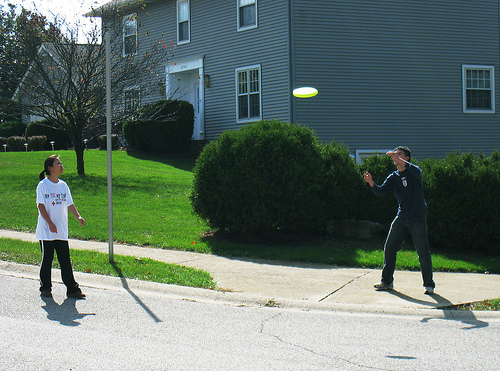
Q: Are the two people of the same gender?
A: No, they are both male and female.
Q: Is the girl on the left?
A: Yes, the girl is on the left of the image.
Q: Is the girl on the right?
A: No, the girl is on the left of the image.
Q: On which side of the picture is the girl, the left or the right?
A: The girl is on the left of the image.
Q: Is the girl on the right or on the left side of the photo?
A: The girl is on the left of the image.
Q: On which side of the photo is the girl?
A: The girl is on the left of the image.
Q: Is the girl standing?
A: Yes, the girl is standing.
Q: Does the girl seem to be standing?
A: Yes, the girl is standing.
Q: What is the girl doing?
A: The girl is standing.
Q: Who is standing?
A: The girl is standing.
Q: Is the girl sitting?
A: No, the girl is standing.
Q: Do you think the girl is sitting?
A: No, the girl is standing.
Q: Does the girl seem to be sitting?
A: No, the girl is standing.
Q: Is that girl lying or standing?
A: The girl is standing.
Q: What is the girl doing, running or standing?
A: The girl is standing.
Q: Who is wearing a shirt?
A: The girl is wearing a shirt.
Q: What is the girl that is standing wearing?
A: The girl is wearing a shirt.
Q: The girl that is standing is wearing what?
A: The girl is wearing a shirt.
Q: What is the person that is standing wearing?
A: The girl is wearing a shirt.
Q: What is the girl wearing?
A: The girl is wearing a shirt.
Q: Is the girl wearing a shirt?
A: Yes, the girl is wearing a shirt.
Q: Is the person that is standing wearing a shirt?
A: Yes, the girl is wearing a shirt.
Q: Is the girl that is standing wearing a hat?
A: No, the girl is wearing a shirt.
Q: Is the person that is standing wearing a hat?
A: No, the girl is wearing a shirt.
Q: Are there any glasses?
A: No, there are no glasses.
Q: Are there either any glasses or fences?
A: No, there are no glasses or fences.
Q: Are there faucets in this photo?
A: No, there are no faucets.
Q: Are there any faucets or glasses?
A: No, there are no faucets or glasses.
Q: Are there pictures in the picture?
A: No, there are no pictures.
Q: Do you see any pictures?
A: No, there are no pictures.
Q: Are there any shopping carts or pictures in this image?
A: No, there are no pictures or shopping carts.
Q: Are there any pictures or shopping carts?
A: No, there are no pictures or shopping carts.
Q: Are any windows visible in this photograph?
A: Yes, there is a window.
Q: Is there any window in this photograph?
A: Yes, there is a window.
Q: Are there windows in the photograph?
A: Yes, there is a window.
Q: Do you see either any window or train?
A: Yes, there is a window.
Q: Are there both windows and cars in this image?
A: No, there is a window but no cars.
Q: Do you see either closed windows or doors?
A: Yes, there is a closed window.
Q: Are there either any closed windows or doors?
A: Yes, there is a closed window.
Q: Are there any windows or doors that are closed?
A: Yes, the window is closed.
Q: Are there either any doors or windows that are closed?
A: Yes, the window is closed.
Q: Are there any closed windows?
A: Yes, there is a closed window.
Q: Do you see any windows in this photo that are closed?
A: Yes, there is a window that is closed.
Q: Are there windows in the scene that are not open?
A: Yes, there is an closed window.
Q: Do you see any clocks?
A: No, there are no clocks.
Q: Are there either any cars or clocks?
A: No, there are no clocks or cars.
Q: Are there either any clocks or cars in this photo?
A: No, there are no clocks or cars.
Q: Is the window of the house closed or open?
A: The window is closed.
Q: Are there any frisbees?
A: Yes, there is a frisbee.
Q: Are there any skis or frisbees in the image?
A: Yes, there is a frisbee.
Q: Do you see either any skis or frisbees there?
A: Yes, there is a frisbee.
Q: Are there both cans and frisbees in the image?
A: No, there is a frisbee but no cans.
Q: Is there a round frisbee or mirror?
A: Yes, there is a round frisbee.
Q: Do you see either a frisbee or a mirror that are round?
A: Yes, the frisbee is round.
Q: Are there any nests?
A: No, there are no nests.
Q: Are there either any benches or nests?
A: No, there are no nests or benches.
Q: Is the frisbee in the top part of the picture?
A: Yes, the frisbee is in the top of the image.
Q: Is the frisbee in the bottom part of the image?
A: No, the frisbee is in the top of the image.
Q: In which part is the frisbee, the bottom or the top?
A: The frisbee is in the top of the image.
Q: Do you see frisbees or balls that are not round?
A: No, there is a frisbee but it is round.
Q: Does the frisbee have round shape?
A: Yes, the frisbee is round.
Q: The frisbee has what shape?
A: The frisbee is round.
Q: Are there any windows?
A: Yes, there is a window.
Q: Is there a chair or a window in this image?
A: Yes, there is a window.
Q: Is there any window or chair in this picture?
A: Yes, there is a window.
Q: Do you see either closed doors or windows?
A: Yes, there is a closed window.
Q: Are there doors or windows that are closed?
A: Yes, the window is closed.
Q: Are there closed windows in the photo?
A: Yes, there is a closed window.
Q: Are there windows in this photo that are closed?
A: Yes, there is a window that is closed.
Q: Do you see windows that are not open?
A: Yes, there is an closed window.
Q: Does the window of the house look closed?
A: Yes, the window is closed.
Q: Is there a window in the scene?
A: Yes, there is a window.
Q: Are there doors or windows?
A: Yes, there is a window.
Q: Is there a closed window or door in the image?
A: Yes, there is a closed window.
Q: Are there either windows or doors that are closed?
A: Yes, the window is closed.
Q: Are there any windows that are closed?
A: Yes, there is a closed window.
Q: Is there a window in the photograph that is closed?
A: Yes, there is a window that is closed.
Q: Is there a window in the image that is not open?
A: Yes, there is an closed window.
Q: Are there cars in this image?
A: No, there are no cars.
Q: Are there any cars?
A: No, there are no cars.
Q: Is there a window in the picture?
A: Yes, there is a window.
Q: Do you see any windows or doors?
A: Yes, there is a window.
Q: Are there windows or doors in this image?
A: Yes, there is a window.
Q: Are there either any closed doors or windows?
A: Yes, there is a closed window.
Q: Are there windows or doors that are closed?
A: Yes, the window is closed.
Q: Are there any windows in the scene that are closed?
A: Yes, there is a window that is closed.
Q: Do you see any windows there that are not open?
A: Yes, there is an closed window.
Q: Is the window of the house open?
A: No, the window is closed.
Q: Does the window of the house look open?
A: No, the window is closed.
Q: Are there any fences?
A: No, there are no fences.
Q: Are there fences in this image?
A: No, there are no fences.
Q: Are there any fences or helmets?
A: No, there are no fences or helmets.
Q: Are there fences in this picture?
A: No, there are no fences.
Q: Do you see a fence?
A: No, there are no fences.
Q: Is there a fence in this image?
A: No, there are no fences.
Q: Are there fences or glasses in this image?
A: No, there are no fences or glasses.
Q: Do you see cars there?
A: No, there are no cars.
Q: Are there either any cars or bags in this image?
A: No, there are no cars or bags.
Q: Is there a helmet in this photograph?
A: No, there are no helmets.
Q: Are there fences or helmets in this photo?
A: No, there are no helmets or fences.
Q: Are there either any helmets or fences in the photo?
A: No, there are no helmets or fences.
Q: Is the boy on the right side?
A: Yes, the boy is on the right of the image.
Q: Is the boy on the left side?
A: No, the boy is on the right of the image.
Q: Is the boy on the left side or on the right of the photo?
A: The boy is on the right of the image.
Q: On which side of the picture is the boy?
A: The boy is on the right of the image.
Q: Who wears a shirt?
A: The boy wears a shirt.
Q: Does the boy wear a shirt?
A: Yes, the boy wears a shirt.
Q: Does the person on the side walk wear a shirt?
A: Yes, the boy wears a shirt.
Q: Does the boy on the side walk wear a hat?
A: No, the boy wears a shirt.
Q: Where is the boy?
A: The boy is on the sidewalk.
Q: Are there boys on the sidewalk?
A: Yes, there is a boy on the sidewalk.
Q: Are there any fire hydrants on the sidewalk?
A: No, there is a boy on the sidewalk.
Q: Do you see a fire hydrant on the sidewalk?
A: No, there is a boy on the sidewalk.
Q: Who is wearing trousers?
A: The boy is wearing trousers.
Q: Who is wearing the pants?
A: The boy is wearing trousers.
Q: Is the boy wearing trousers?
A: Yes, the boy is wearing trousers.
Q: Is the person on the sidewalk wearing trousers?
A: Yes, the boy is wearing trousers.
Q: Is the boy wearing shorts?
A: No, the boy is wearing trousers.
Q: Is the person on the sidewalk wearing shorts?
A: No, the boy is wearing trousers.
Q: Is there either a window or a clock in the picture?
A: Yes, there is a window.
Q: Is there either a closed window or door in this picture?
A: Yes, there is a closed window.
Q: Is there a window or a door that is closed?
A: Yes, the window is closed.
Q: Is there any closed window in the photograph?
A: Yes, there is a closed window.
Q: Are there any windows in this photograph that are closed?
A: Yes, there is a window that is closed.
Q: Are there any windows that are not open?
A: Yes, there is an closed window.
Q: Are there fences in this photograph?
A: No, there are no fences.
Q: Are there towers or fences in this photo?
A: No, there are no fences or towers.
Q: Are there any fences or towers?
A: No, there are no fences or towers.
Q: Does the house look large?
A: Yes, the house is large.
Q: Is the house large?
A: Yes, the house is large.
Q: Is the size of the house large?
A: Yes, the house is large.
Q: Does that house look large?
A: Yes, the house is large.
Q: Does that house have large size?
A: Yes, the house is large.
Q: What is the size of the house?
A: The house is large.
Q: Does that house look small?
A: No, the house is large.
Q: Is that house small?
A: No, the house is large.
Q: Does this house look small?
A: No, the house is large.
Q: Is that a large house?
A: Yes, that is a large house.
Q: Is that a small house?
A: No, that is a large house.